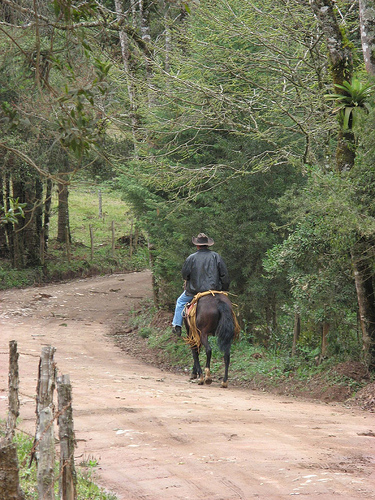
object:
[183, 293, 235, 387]
horse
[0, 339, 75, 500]
fence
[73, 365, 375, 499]
road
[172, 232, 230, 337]
man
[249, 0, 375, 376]
tree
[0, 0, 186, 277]
trees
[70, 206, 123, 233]
grass